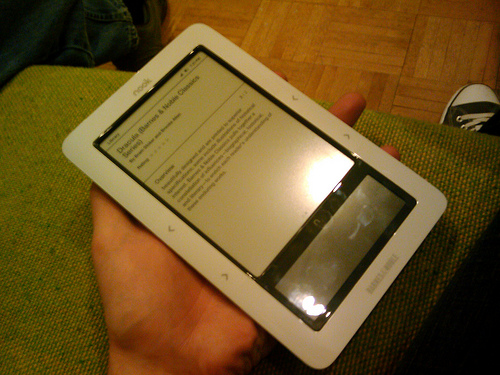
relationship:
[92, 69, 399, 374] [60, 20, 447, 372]
person holding tablet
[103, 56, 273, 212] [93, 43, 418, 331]
text on screen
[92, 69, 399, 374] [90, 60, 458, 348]
person holding reader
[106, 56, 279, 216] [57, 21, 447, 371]
text on electronic book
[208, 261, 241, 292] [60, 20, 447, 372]
button on tablet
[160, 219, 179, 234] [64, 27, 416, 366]
button on tablet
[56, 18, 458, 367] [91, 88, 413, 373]
electronic book on hand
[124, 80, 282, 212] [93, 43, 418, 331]
words on screen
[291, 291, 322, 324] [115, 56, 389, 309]
glare on screen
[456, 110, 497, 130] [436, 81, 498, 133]
laces on shoe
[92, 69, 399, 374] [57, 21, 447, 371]
person holding electronic book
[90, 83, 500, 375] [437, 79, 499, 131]
person wearing shoe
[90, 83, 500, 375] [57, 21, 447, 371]
person holding electronic book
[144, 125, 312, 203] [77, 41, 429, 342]
screen on a tablet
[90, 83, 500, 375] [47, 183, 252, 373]
person has a hand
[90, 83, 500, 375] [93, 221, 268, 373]
person has a palm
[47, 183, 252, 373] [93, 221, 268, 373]
hand has a palm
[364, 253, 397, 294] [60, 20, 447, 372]
logo on a tablet